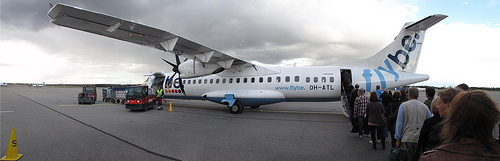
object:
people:
[421, 90, 498, 161]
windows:
[292, 75, 300, 83]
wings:
[48, 1, 303, 71]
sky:
[2, 0, 500, 88]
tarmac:
[0, 86, 500, 161]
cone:
[3, 124, 25, 159]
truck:
[123, 84, 167, 111]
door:
[337, 66, 357, 97]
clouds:
[1, 3, 315, 75]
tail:
[357, 11, 450, 103]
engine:
[159, 49, 220, 82]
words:
[363, 23, 420, 93]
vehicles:
[76, 86, 101, 106]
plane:
[48, 0, 448, 114]